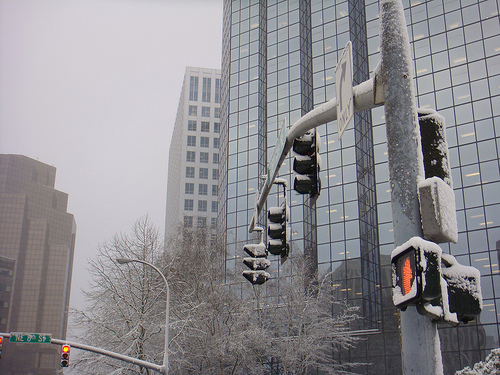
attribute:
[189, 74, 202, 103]
window — taller, at top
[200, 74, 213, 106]
window — taller, at top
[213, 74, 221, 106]
window — taller, at top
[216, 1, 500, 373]
building — made of glass, tall